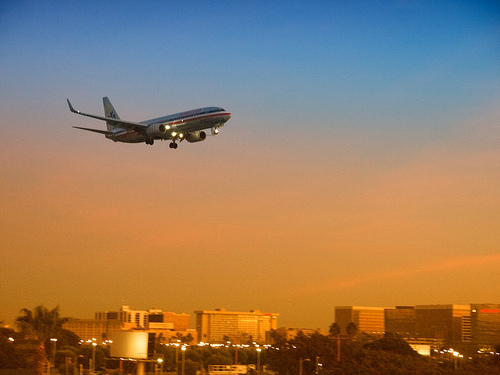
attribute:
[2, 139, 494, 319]
cloud — white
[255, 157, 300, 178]
clouds — white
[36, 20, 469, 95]
sky — white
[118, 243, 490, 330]
glow — orange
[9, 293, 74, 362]
tree — tall palm 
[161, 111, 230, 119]
stripe — red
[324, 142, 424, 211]
clouds — white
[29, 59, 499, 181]
clouds — white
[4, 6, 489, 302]
sky — blue, colored, clear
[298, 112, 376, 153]
sky — blue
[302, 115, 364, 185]
clouds — white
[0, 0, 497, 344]
sky — blue, white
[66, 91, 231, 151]
airplane — commerical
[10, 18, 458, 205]
flight — dusk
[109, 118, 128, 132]
marks — white , Red 